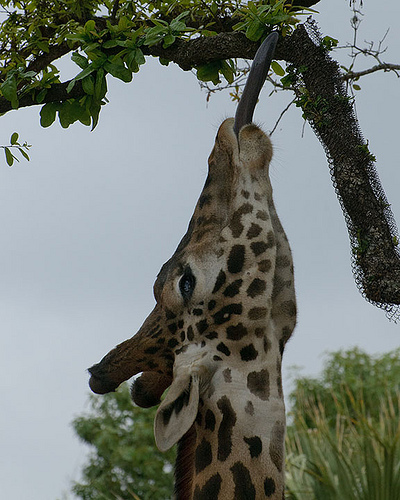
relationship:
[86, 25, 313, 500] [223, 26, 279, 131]
giraffe sticking out tongue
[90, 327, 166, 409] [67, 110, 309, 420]
giraffe's horn on a head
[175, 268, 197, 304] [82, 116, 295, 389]
eye on a head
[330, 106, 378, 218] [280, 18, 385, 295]
mesh on a branch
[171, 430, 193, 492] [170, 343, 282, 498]
hair on a back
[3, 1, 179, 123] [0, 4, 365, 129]
leaves on a tree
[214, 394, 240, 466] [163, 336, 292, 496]
spot on a neck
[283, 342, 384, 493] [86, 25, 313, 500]
trees behind a giraffe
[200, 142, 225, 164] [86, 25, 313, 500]
nose on a giraffe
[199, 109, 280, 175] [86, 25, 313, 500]
mouth on a giraffe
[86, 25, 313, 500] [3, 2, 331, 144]
giraffe eating leaves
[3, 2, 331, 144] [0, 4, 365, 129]
leaves from a tree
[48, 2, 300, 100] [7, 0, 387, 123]
leaves on branch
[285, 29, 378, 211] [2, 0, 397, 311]
mesh on tree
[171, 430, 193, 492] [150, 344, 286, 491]
hair on back of neck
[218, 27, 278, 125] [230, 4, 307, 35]
tongue reaching for leaf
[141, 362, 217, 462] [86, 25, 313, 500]
ear of giraffe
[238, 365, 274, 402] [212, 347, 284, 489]
spot on fur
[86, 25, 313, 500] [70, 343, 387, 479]
giraffe at a safari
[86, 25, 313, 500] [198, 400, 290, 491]
giraffe with fur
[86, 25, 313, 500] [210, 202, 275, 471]
giraffe with spots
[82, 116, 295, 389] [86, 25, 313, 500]
head of a giraffe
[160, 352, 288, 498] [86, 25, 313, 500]
neck of a giraffe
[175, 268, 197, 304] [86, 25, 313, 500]
eye of a giraffe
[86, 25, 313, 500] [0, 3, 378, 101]
giraffe looking towards tree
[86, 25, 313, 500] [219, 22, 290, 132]
giraffe eating vegetable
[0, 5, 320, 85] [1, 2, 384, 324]
leaves of a large tree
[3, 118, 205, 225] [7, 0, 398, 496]
sky at a safari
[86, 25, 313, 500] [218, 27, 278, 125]
giraffe with tongue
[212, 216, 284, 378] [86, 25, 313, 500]
spots on a giraffe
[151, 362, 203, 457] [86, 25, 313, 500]
ear of a giraffe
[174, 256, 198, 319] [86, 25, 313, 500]
eye of a giraffe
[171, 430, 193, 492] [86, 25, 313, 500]
hair on a giraffe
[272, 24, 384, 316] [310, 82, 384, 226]
tree branch in netting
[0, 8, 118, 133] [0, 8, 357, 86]
leaves on a tree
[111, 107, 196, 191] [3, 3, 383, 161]
patch of sky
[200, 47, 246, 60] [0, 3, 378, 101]
bark of tree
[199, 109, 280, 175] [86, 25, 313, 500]
mouth of a giraffe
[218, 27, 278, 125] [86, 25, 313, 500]
tongue of a giraffe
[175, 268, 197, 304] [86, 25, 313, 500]
eye of giraffe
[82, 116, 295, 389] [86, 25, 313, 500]
head of giraffe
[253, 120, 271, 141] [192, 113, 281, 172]
hair on mouth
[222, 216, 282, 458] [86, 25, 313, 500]
spots on giraffe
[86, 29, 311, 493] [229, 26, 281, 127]
giraffe has tongue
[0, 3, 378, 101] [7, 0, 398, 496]
tree in a safari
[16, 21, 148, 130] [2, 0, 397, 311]
leaves growing on tree